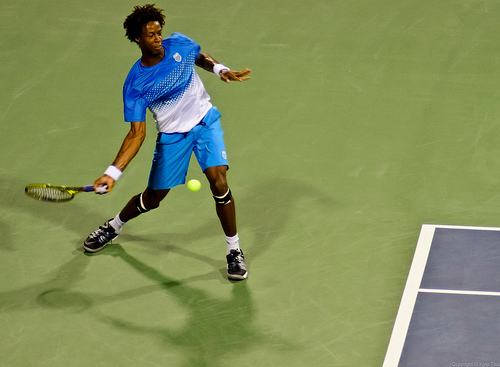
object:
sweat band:
[103, 162, 122, 181]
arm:
[92, 112, 144, 190]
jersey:
[123, 31, 207, 151]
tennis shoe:
[212, 238, 266, 288]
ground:
[451, 125, 484, 176]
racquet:
[18, 144, 112, 226]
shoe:
[226, 247, 248, 279]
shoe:
[83, 217, 121, 252]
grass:
[298, 116, 395, 243]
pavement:
[301, 54, 498, 258]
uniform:
[120, 30, 230, 190]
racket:
[12, 172, 95, 214]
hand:
[90, 170, 118, 197]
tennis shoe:
[90, 219, 115, 254]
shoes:
[49, 207, 305, 310]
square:
[389, 227, 499, 366]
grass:
[2, 3, 499, 365]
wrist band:
[211, 64, 226, 76]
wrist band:
[105, 161, 122, 180]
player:
[25, 2, 252, 279]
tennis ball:
[185, 178, 198, 189]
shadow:
[80, 243, 284, 365]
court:
[0, 2, 498, 365]